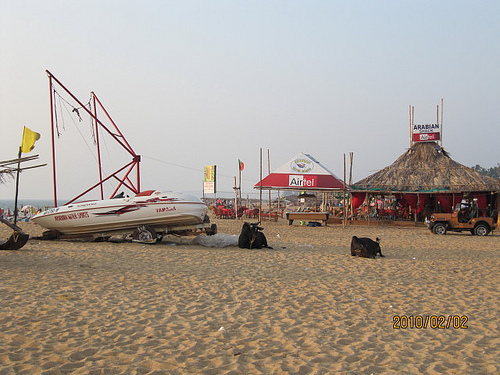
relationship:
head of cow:
[242, 222, 259, 242] [240, 216, 274, 248]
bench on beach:
[258, 203, 332, 237] [2, 235, 498, 373]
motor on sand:
[232, 220, 271, 252] [0, 203, 499, 371]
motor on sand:
[350, 231, 385, 258] [0, 203, 499, 371]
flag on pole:
[18, 124, 40, 155] [2, 152, 25, 222]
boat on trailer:
[36, 200, 206, 230] [7, 193, 39, 248]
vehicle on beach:
[419, 195, 496, 237] [0, 198, 497, 373]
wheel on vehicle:
[474, 219, 491, 241] [422, 197, 493, 237]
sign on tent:
[287, 167, 335, 192] [251, 139, 357, 242]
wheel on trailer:
[138, 231, 156, 243] [31, 71, 216, 248]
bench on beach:
[0, 217, 499, 375] [5, 212, 497, 341]